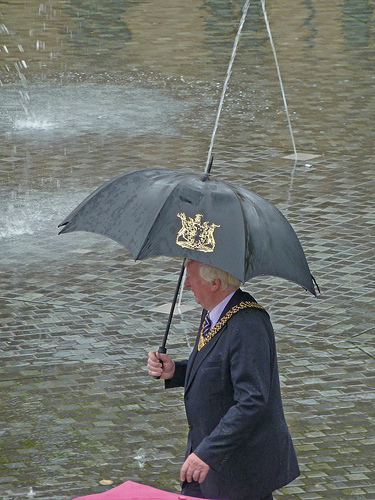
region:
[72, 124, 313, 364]
a black open umbrella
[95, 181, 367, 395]
a black umbrella with gold emblem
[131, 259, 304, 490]
a man wearing a suit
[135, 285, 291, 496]
a man wearing a black suit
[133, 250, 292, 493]
a man walking otuside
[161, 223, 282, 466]
a man under the umbrella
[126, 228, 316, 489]
this is a man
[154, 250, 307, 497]
man wearing a suit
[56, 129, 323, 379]
this is an umbrella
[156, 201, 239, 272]
gold emblem on umbrella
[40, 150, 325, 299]
the umbrella is black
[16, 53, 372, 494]
the ground is wet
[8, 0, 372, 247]
this is a fountain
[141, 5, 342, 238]
water from the fountain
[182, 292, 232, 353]
man wearing a white shirt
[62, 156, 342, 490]
man is under the umbrella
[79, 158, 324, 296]
Top of a black umbrella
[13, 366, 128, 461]
Damp gray brick walkway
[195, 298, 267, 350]
Black and gold chain or strap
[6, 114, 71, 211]
Rain falling to the ground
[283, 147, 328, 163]
A gray tile on the ground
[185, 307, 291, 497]
A suit jacket and tie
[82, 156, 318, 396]
A gray haired man holding an umbrella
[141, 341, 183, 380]
A right hand gripping a black handle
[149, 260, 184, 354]
A thin black umbrella stick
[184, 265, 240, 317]
The profile of a gray haired man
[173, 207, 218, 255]
symbol on side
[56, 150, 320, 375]
a black umbrella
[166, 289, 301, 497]
a blue suit coat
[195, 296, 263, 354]
a gold embroidery around neck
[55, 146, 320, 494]
a man walking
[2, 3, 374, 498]
the wet grounds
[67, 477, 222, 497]
a red object next to man walking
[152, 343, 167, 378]
handle of umbrella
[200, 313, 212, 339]
a tie around neck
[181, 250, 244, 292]
the grey hair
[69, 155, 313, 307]
the umbrella is black